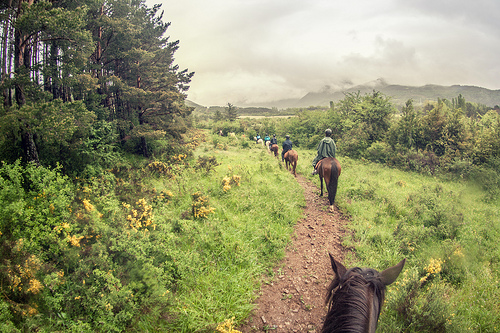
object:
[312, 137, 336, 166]
robe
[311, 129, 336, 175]
people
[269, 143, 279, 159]
horses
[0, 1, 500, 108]
sky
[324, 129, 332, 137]
head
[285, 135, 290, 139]
head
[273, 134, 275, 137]
head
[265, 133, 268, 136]
head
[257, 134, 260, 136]
head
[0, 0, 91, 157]
pine trees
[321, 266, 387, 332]
mane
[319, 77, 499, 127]
mountains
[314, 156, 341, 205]
horse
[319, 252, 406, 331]
horse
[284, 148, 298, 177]
horse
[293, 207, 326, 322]
trail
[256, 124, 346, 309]
path